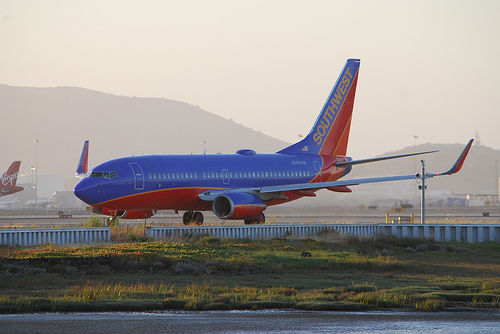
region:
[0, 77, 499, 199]
Mountains in the background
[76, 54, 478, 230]
Blue and red jet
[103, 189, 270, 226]
Plane has two jet engines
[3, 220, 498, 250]
Fence in front of plane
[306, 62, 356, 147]
Logo of Airline company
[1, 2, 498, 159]
Very hazy sky above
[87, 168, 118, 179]
Window for the pilots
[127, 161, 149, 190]
Door to the plane is closed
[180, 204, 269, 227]
Landing gear is down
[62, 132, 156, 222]
front of a plane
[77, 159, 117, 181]
window of a plane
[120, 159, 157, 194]
door of a plane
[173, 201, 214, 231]
wheel of a plane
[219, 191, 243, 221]
turbine of a plane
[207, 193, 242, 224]
engine of a plane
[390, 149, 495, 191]
wing of a plane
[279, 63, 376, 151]
wing of a plane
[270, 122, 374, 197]
tail of a plane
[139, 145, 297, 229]
body of a plane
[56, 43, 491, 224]
the plane on the runway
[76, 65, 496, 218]
the plane is blue and red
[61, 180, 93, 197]
the nose of the plane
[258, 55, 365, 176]
the tail of the plane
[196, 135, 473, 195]
the wing of the plane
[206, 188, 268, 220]
the engine under the wing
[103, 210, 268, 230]
the landing gear is down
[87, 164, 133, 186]
the cockpit of the plane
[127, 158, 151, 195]
the forward hatch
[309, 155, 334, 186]
the rear hatch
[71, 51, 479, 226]
an airplane in the runway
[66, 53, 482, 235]
a blue and red airplane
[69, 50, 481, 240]
a Southwest airplane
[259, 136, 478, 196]
a wing of the airplane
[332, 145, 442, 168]
a horizontal stabilizer of the plane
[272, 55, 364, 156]
a vertical stabilizer of the plane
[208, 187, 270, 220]
an engine of the plane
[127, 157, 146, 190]
a door of an airplane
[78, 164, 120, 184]
a cockpit of the airplane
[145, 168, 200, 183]
windows of the airplane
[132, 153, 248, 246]
this is a plane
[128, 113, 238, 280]
the plane is blue and red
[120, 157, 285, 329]
the plane is southwest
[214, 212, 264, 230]
this is a jet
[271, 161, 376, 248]
this is a wing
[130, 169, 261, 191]
this is a window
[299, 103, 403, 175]
this is a logo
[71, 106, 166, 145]
this is a mountain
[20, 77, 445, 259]
a red and blue airplane on the tarmac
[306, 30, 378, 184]
the name of airplane in yellow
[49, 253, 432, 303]
the empty field by the airplane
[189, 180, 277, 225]
the engine of the airplane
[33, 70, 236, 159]
the mountains in the background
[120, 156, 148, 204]
the passenger door of the airplane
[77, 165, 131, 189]
the cockpit of the airplane